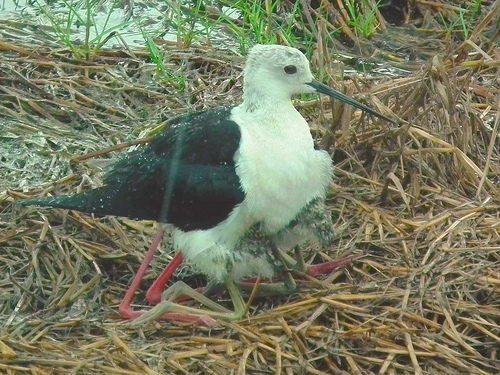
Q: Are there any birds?
A: Yes, there is a bird.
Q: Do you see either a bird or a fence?
A: Yes, there is a bird.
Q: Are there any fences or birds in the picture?
A: Yes, there is a bird.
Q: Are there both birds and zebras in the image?
A: No, there is a bird but no zebras.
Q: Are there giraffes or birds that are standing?
A: Yes, the bird is standing.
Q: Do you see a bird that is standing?
A: Yes, there is a bird that is standing.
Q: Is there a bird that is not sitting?
A: Yes, there is a bird that is standing.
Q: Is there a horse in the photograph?
A: No, there are no horses.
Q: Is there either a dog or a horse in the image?
A: No, there are no horses or dogs.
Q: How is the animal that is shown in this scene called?
A: The animal is a bird.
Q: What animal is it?
A: The animal is a bird.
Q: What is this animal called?
A: This is a bird.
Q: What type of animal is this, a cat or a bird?
A: This is a bird.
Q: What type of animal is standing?
A: The animal is a bird.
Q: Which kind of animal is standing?
A: The animal is a bird.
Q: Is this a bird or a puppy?
A: This is a bird.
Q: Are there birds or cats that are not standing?
A: No, there is a bird but it is standing.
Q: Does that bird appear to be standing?
A: Yes, the bird is standing.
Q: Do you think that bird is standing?
A: Yes, the bird is standing.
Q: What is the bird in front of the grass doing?
A: The bird is standing.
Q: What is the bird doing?
A: The bird is standing.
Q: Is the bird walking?
A: No, the bird is standing.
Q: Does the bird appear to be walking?
A: No, the bird is standing.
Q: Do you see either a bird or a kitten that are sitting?
A: No, there is a bird but it is standing.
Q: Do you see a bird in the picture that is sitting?
A: No, there is a bird but it is standing.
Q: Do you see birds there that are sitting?
A: No, there is a bird but it is standing.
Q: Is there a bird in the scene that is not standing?
A: No, there is a bird but it is standing.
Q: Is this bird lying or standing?
A: The bird is standing.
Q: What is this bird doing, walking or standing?
A: The bird is standing.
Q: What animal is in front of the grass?
A: The animal is a bird.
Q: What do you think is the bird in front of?
A: The bird is in front of the grass.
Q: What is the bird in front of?
A: The bird is in front of the grass.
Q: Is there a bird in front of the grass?
A: Yes, there is a bird in front of the grass.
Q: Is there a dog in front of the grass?
A: No, there is a bird in front of the grass.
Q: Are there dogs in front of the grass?
A: No, there is a bird in front of the grass.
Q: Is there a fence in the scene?
A: No, there are no fences.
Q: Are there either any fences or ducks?
A: No, there are no fences or ducks.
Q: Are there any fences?
A: No, there are no fences.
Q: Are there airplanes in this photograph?
A: No, there are no airplanes.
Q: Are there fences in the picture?
A: No, there are no fences.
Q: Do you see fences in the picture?
A: No, there are no fences.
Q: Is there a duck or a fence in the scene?
A: No, there are no fences or ducks.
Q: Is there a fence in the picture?
A: No, there are no fences.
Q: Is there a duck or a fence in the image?
A: No, there are no fences or ducks.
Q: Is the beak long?
A: Yes, the beak is long.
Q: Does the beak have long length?
A: Yes, the beak is long.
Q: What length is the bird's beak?
A: The beak is long.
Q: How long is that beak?
A: The beak is long.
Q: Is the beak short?
A: No, the beak is long.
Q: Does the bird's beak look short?
A: No, the beak is long.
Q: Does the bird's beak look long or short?
A: The beak is long.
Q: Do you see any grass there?
A: Yes, there is grass.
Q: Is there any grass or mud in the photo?
A: Yes, there is grass.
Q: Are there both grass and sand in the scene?
A: No, there is grass but no sand.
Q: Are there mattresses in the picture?
A: No, there are no mattresses.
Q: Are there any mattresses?
A: No, there are no mattresses.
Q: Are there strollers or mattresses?
A: No, there are no mattresses or strollers.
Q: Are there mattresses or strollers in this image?
A: No, there are no mattresses or strollers.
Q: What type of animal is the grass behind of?
A: The grass is behind the bird.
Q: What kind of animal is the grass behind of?
A: The grass is behind the bird.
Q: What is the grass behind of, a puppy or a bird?
A: The grass is behind a bird.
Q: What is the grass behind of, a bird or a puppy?
A: The grass is behind a bird.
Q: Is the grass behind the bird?
A: Yes, the grass is behind the bird.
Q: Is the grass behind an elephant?
A: No, the grass is behind the bird.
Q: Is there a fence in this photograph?
A: No, there are no fences.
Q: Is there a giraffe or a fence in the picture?
A: No, there are no fences or giraffes.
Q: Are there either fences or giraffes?
A: No, there are no fences or giraffes.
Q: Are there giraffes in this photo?
A: No, there are no giraffes.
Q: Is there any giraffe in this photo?
A: No, there are no giraffes.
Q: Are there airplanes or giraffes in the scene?
A: No, there are no giraffes or airplanes.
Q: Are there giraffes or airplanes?
A: No, there are no giraffes or airplanes.